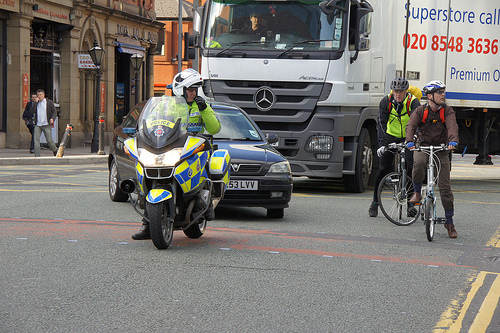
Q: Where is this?
A: This is at the street.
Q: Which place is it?
A: It is a street.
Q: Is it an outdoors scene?
A: Yes, it is outdoors.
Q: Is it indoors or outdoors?
A: It is outdoors.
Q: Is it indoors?
A: No, it is outdoors.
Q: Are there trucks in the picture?
A: Yes, there is a truck.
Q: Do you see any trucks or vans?
A: Yes, there is a truck.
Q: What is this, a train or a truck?
A: This is a truck.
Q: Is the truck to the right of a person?
A: Yes, the truck is to the right of a person.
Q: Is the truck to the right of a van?
A: No, the truck is to the right of a person.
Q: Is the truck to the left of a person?
A: No, the truck is to the right of a person.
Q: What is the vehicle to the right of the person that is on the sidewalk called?
A: The vehicle is a truck.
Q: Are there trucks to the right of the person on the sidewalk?
A: Yes, there is a truck to the right of the person.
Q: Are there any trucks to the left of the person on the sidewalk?
A: No, the truck is to the right of the person.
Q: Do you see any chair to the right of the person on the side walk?
A: No, there is a truck to the right of the person.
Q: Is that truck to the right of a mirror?
A: No, the truck is to the right of the person.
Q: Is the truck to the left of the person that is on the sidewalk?
A: No, the truck is to the right of the person.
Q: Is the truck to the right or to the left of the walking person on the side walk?
A: The truck is to the right of the person.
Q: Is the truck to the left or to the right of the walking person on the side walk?
A: The truck is to the right of the person.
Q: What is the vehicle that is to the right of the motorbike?
A: The vehicle is a truck.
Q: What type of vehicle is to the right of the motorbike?
A: The vehicle is a truck.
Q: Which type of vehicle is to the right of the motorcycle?
A: The vehicle is a truck.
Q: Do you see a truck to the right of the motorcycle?
A: Yes, there is a truck to the right of the motorcycle.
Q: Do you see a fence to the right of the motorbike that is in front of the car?
A: No, there is a truck to the right of the motorbike.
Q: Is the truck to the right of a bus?
A: No, the truck is to the right of a motorcycle.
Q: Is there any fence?
A: No, there are no fences.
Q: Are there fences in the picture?
A: No, there are no fences.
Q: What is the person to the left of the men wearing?
A: The person is wearing a helmet.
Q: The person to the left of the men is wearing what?
A: The person is wearing a helmet.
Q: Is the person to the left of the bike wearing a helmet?
A: Yes, the person is wearing a helmet.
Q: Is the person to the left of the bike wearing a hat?
A: No, the person is wearing a helmet.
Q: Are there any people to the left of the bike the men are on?
A: Yes, there is a person to the left of the bike.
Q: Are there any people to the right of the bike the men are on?
A: No, the person is to the left of the bike.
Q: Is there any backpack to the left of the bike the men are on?
A: No, there is a person to the left of the bike.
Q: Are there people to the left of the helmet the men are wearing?
A: Yes, there is a person to the left of the helmet.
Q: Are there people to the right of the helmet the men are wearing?
A: No, the person is to the left of the helmet.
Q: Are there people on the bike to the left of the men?
A: Yes, there is a person on the bike.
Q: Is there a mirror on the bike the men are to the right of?
A: No, there is a person on the bike.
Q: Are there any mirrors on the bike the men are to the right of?
A: No, there is a person on the bike.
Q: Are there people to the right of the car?
A: Yes, there is a person to the right of the car.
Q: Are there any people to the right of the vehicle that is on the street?
A: Yes, there is a person to the right of the car.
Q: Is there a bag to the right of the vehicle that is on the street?
A: No, there is a person to the right of the car.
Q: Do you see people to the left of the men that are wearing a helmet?
A: Yes, there is a person to the left of the men.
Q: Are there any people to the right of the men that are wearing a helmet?
A: No, the person is to the left of the men.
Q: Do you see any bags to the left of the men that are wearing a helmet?
A: No, there is a person to the left of the men.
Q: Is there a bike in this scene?
A: Yes, there is a bike.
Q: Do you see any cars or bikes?
A: Yes, there is a bike.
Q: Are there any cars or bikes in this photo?
A: Yes, there is a bike.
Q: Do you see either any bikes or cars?
A: Yes, there is a bike.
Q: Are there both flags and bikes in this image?
A: No, there is a bike but no flags.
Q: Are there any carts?
A: No, there are no carts.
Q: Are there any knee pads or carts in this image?
A: No, there are no carts or knee pads.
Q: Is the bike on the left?
A: No, the bike is on the right of the image.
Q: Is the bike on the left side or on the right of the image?
A: The bike is on the right of the image.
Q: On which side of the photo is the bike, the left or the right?
A: The bike is on the right of the image.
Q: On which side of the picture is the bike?
A: The bike is on the right of the image.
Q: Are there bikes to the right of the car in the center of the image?
A: Yes, there is a bike to the right of the car.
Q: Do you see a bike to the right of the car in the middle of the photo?
A: Yes, there is a bike to the right of the car.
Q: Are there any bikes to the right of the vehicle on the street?
A: Yes, there is a bike to the right of the car.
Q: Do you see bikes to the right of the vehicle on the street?
A: Yes, there is a bike to the right of the car.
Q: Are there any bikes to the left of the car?
A: No, the bike is to the right of the car.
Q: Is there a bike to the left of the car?
A: No, the bike is to the right of the car.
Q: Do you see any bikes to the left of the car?
A: No, the bike is to the right of the car.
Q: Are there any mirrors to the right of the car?
A: No, there is a bike to the right of the car.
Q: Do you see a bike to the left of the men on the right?
A: Yes, there is a bike to the left of the men.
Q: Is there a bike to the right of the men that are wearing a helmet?
A: No, the bike is to the left of the men.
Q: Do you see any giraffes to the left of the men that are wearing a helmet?
A: No, there is a bike to the left of the men.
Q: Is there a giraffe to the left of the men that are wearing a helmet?
A: No, there is a bike to the left of the men.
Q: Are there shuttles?
A: No, there are no shuttles.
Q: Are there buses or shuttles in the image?
A: No, there are no shuttles or buses.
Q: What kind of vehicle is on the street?
A: The vehicle is a car.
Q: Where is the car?
A: The car is on the street.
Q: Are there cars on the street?
A: Yes, there is a car on the street.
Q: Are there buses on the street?
A: No, there is a car on the street.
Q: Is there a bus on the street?
A: No, there is a car on the street.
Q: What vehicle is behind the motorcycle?
A: The vehicle is a car.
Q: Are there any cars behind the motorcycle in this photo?
A: Yes, there is a car behind the motorcycle.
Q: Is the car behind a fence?
A: No, the car is behind a motorcycle.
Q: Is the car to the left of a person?
A: No, the car is to the right of a person.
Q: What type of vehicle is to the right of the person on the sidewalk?
A: The vehicle is a car.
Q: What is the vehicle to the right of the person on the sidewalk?
A: The vehicle is a car.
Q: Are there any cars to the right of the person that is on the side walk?
A: Yes, there is a car to the right of the person.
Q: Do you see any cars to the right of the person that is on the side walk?
A: Yes, there is a car to the right of the person.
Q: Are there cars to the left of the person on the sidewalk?
A: No, the car is to the right of the person.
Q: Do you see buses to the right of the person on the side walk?
A: No, there is a car to the right of the person.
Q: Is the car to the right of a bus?
A: No, the car is to the right of the person.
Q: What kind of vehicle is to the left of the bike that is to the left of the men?
A: The vehicle is a car.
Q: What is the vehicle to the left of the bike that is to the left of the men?
A: The vehicle is a car.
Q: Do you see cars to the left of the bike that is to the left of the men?
A: Yes, there is a car to the left of the bike.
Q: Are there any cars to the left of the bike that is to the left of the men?
A: Yes, there is a car to the left of the bike.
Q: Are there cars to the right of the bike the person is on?
A: No, the car is to the left of the bike.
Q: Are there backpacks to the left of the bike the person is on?
A: No, there is a car to the left of the bike.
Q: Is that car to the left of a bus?
A: No, the car is to the left of the bike.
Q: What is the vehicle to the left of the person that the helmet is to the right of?
A: The vehicle is a car.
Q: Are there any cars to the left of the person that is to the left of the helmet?
A: Yes, there is a car to the left of the person.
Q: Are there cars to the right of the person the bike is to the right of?
A: No, the car is to the left of the person.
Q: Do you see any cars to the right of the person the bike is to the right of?
A: No, the car is to the left of the person.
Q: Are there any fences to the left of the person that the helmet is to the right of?
A: No, there is a car to the left of the person.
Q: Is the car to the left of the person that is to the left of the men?
A: Yes, the car is to the left of the person.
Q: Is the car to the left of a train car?
A: No, the car is to the left of the person.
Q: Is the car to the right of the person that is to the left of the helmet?
A: No, the car is to the left of the person.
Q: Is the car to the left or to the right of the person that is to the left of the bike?
A: The car is to the left of the person.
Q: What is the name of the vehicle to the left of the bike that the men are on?
A: The vehicle is a car.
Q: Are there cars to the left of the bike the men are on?
A: Yes, there is a car to the left of the bike.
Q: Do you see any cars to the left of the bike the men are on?
A: Yes, there is a car to the left of the bike.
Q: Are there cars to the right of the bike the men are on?
A: No, the car is to the left of the bike.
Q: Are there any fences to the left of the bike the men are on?
A: No, there is a car to the left of the bike.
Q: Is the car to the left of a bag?
A: No, the car is to the left of a bike.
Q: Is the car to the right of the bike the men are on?
A: No, the car is to the left of the bike.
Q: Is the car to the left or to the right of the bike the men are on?
A: The car is to the left of the bike.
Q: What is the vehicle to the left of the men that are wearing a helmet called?
A: The vehicle is a car.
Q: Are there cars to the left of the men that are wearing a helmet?
A: Yes, there is a car to the left of the men.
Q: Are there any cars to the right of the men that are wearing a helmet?
A: No, the car is to the left of the men.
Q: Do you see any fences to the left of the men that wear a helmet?
A: No, there is a car to the left of the men.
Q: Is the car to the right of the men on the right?
A: No, the car is to the left of the men.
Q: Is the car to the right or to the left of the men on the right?
A: The car is to the left of the men.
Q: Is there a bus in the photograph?
A: No, there are no buses.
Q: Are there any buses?
A: No, there are no buses.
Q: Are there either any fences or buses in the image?
A: No, there are no buses or fences.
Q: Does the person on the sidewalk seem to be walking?
A: Yes, the person is walking.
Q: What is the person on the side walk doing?
A: The person is walking.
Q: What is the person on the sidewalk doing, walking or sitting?
A: The person is walking.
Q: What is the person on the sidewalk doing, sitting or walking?
A: The person is walking.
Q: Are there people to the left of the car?
A: Yes, there is a person to the left of the car.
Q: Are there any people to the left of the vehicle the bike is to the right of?
A: Yes, there is a person to the left of the car.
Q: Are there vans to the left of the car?
A: No, there is a person to the left of the car.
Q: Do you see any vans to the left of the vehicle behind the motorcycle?
A: No, there is a person to the left of the car.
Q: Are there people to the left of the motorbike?
A: Yes, there is a person to the left of the motorbike.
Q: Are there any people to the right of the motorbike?
A: No, the person is to the left of the motorbike.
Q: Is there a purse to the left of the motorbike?
A: No, there is a person to the left of the motorbike.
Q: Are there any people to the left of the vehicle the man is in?
A: Yes, there is a person to the left of the truck.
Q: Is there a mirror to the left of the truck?
A: No, there is a person to the left of the truck.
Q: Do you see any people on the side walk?
A: Yes, there is a person on the side walk.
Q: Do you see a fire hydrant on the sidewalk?
A: No, there is a person on the sidewalk.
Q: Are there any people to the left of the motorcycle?
A: Yes, there is a person to the left of the motorcycle.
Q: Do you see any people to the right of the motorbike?
A: No, the person is to the left of the motorbike.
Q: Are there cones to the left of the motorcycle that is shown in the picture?
A: No, there is a person to the left of the motorcycle.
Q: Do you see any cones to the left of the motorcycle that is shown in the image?
A: No, there is a person to the left of the motorcycle.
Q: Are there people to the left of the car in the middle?
A: Yes, there is a person to the left of the car.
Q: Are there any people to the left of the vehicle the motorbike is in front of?
A: Yes, there is a person to the left of the car.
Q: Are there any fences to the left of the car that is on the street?
A: No, there is a person to the left of the car.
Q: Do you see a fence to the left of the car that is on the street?
A: No, there is a person to the left of the car.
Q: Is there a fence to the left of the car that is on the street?
A: No, there is a person to the left of the car.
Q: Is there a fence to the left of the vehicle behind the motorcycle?
A: No, there is a person to the left of the car.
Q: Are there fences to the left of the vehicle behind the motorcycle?
A: No, there is a person to the left of the car.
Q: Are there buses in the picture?
A: No, there are no buses.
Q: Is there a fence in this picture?
A: No, there are no fences.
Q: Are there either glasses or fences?
A: No, there are no fences or glasses.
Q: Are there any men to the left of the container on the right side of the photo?
A: Yes, there is a man to the left of the box.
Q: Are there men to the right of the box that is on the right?
A: No, the man is to the left of the box.